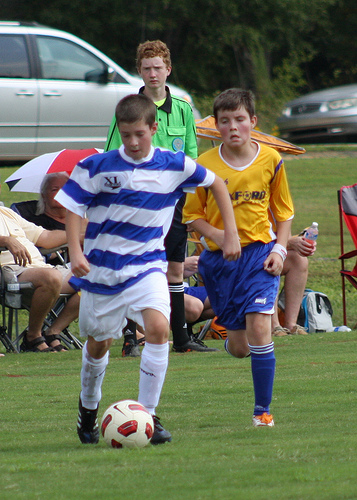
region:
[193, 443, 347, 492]
The grass is green.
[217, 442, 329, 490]
The grass is short.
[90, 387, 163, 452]
The ball is red and white.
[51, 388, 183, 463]
The person is wearing black shoes.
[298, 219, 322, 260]
The person is holding a plastic bottle.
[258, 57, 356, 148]
Cars are in the background.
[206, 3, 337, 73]
Trees are in the background.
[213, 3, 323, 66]
The trees have leaves on them.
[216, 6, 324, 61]
The trees are green.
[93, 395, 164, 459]
The ball is a soccer ball.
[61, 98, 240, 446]
a young boy playing soccer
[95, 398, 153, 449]
a red and white soccer ball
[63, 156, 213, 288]
a blue and white striped polo shirt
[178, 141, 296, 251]
a yellow soccer jersey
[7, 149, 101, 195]
a red white and black umbrella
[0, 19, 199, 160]
a parked silver minivan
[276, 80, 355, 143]
a parked silver car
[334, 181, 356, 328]
a red folding chair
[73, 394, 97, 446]
a black and white soccer shoe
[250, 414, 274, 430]
an orange and white soccer shoe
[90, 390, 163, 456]
The ball is round.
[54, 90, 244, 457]
The boy is playing soccer.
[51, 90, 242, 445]
The boy is wearing shin guards.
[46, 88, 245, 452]
The boy is wearing a shirt.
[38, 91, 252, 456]
Boy's shirt is striped.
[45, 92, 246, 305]
The shirt is blue and white.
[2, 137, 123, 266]
Woman is holding an umbrella.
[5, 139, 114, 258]
The umbrella is open.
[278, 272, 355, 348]
A bag sitting on the grass.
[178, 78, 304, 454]
young boy running on soccer field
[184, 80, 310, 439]
boy wearing yellow shirt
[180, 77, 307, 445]
boy wearing blue shorts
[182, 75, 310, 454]
boy with short dark hair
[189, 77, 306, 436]
boy wearing white wristband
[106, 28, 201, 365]
boy wearing green collared shirt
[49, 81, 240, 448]
boy kicking soccer ball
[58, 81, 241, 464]
boy wearing blue and white striped shirt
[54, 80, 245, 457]
boy wearing white shirt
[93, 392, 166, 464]
red and white soccer ball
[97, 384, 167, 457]
A red and white soccer ball.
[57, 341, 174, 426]
White shin guards.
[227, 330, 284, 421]
Blue shin guards.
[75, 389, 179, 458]
Black shoes.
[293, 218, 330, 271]
A plastic water bottle.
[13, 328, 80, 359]
A pair of mens sandals.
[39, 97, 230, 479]
A boy about to kick a soccer ball.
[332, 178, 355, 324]
A red chair.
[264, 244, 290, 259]
A white wristband.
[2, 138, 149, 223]
A red, white, and blue umbrella.